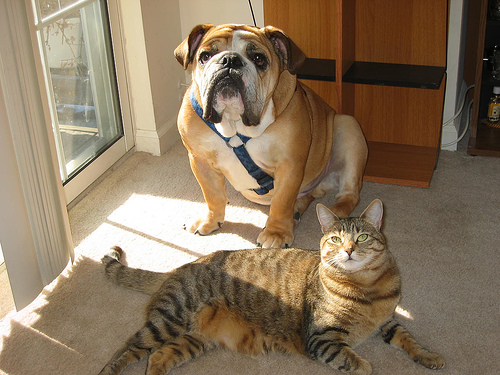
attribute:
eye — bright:
[321, 228, 342, 249]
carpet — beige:
[426, 233, 463, 328]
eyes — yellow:
[320, 227, 372, 244]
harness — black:
[238, 158, 284, 196]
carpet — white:
[431, 208, 481, 286]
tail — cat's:
[91, 238, 174, 297]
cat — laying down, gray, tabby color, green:
[78, 199, 452, 366]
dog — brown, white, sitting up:
[161, 17, 387, 250]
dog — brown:
[170, 21, 377, 248]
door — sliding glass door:
[19, 0, 149, 184]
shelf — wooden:
[265, 51, 448, 96]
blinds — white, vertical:
[0, 3, 96, 310]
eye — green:
[324, 228, 344, 248]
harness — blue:
[192, 99, 284, 193]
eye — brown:
[248, 48, 272, 77]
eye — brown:
[196, 40, 214, 61]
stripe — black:
[301, 323, 349, 336]